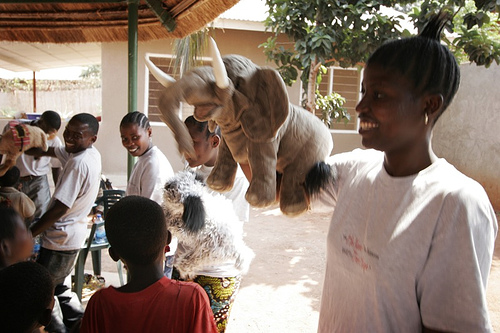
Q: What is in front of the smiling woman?
A: A toy elephant.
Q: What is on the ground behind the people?
A: Shadows.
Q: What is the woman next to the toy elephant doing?
A: Smiling.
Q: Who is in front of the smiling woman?
A: A boy with a red shirt.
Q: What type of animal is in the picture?
A: A grey stuffed elephant.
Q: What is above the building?
A: A brown awning.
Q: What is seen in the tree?
A: Green leaves.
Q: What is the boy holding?
A: Gray stuffed animal puppet.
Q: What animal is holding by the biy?
A: Elephant.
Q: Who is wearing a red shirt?
A: A boy.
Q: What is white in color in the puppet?
A: Elephant horns.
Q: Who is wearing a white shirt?
A: The boy.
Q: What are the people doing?
A: Smiling each other.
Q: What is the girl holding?
A: An elephant.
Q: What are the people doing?
A: Celebrating.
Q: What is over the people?
A: A canopy.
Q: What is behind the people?
A: A house.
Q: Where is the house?
A: Behind the people.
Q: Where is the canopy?
A: Above the people.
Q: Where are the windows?
A: On the house.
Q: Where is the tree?
A: In front of the house.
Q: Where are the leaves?
A: On the tree.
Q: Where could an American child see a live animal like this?
A: Zoo.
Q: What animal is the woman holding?
A: An elephant.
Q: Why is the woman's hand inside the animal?
A: It's a puppet.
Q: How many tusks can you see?
A: 2.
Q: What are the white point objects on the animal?
A: Tusks.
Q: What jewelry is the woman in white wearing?
A: Earrings.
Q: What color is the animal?
A: Gray.